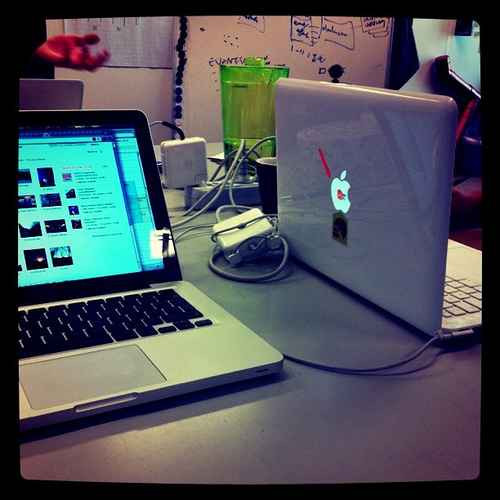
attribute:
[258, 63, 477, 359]
computer — white, present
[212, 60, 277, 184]
cup — green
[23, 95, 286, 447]
computer — on, present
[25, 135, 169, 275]
screen — bright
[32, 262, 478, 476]
table — gray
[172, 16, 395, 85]
board — white